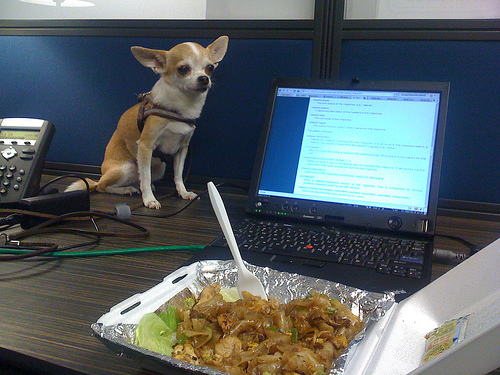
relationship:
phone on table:
[1, 108, 64, 218] [0, 156, 499, 373]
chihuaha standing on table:
[61, 30, 234, 211] [35, 174, 256, 328]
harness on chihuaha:
[134, 89, 201, 131] [61, 30, 234, 211]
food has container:
[138, 282, 363, 372] [93, 227, 485, 371]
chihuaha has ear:
[61, 30, 234, 211] [131, 42, 173, 76]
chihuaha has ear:
[61, 30, 234, 211] [202, 34, 232, 58]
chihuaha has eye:
[61, 30, 234, 211] [175, 63, 193, 77]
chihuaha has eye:
[61, 30, 234, 211] [201, 63, 216, 75]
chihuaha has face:
[61, 30, 234, 211] [169, 46, 241, 97]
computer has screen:
[175, 77, 451, 309] [255, 74, 445, 228]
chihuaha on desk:
[61, 30, 234, 211] [4, 163, 484, 373]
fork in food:
[196, 181, 273, 304] [169, 280, 368, 374]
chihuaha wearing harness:
[61, 30, 234, 211] [131, 90, 199, 154]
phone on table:
[0, 115, 56, 205] [45, 149, 437, 373]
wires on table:
[2, 172, 207, 263] [1, 248, 201, 373]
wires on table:
[213, 176, 250, 192] [1, 248, 201, 373]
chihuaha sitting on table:
[61, 30, 234, 211] [16, 187, 281, 373]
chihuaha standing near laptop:
[65, 36, 230, 209] [192, 75, 458, 267]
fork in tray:
[204, 179, 274, 304] [86, 232, 498, 372]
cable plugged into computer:
[0, 235, 210, 256] [175, 77, 451, 309]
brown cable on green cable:
[29, 232, 64, 335] [64, 240, 85, 268]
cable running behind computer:
[198, 186, 475, 264] [175, 77, 451, 309]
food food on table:
[138, 282, 364, 375] [0, 156, 499, 373]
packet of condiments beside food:
[421, 310, 466, 364] [171, 270, 364, 374]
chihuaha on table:
[61, 30, 234, 211] [21, 211, 229, 316]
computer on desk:
[175, 77, 451, 309] [0, 161, 500, 375]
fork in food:
[204, 179, 274, 304] [104, 254, 396, 374]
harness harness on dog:
[131, 89, 201, 167] [43, 32, 259, 223]